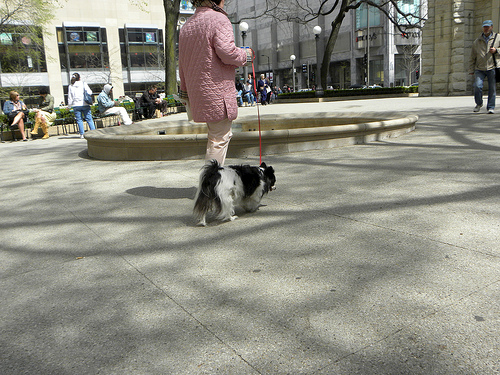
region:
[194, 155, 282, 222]
black and white dog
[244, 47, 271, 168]
red leash of black and white dog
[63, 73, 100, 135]
woman wearing white coat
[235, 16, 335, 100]
street lights on sidewalk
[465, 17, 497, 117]
man wearing ball cap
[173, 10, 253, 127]
pink jacket of woman walking dog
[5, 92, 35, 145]
woman with her legs crossed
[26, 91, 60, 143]
woman wearing yellow boots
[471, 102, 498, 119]
shoes of man walking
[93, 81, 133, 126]
man with his hood up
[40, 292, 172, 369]
salt and peppered textured concrete sidewalk slab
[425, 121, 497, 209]
tree limb shadows cast upon concrete walkway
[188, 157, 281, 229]
small long haired black and white dog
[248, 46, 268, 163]
red taut dog leash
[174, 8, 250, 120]
heavy pink winter coat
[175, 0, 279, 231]
woman taking dog for a walk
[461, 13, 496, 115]
man in blue jeans and tan jacket walking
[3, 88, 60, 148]
two women sitting on bench talking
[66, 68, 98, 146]
woman in blue jeans and white coat looking down street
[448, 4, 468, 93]
rough white stone column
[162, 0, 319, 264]
woman walking her dog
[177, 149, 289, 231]
the dog is black and white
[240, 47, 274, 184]
the leash is red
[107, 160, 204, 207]
shadow of the woman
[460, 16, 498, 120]
man walking towards the woman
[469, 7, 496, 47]
man wearing a baseball hat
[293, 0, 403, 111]
a black tree ahead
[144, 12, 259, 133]
woman wearing a pink coat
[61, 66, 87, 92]
woman wearing a ponytail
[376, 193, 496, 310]
the sun is on the ground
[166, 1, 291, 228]
person walking a dog on a leash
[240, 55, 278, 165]
a red leash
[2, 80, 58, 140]
two women sitting on a stone bench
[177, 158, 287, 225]
a white and black dog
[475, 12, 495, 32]
man wearing a blue cap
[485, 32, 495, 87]
man carrying a black bag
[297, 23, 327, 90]
a lamppost with a white bulb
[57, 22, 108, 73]
grilled windows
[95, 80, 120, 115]
man wearing a hoodie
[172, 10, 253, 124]
person wearing a pink coat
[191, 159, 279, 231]
black and white dog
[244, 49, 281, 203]
red leash on dog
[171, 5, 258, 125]
person wearing a pink jacket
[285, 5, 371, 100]
tree in park with bare branches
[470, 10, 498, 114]
man walking toward person with dog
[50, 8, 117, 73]
window in building behind park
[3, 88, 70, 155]
people sitting on a bench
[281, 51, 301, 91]
light post by the road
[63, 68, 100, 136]
woman wearing white jacket and blue jeans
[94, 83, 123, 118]
person sitting down wearing a hoodie